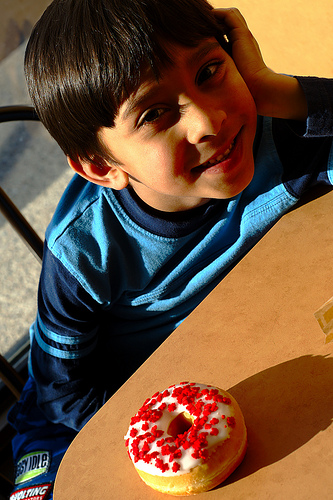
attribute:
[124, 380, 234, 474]
icing — red, white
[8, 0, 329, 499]
boy — pictured, light-skinned, sitting, young, smiling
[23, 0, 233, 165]
hair — pictured, short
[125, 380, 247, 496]
doughnut — pictured, creamy, sitting, brown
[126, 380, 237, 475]
cream — white, pictured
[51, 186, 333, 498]
table — pictured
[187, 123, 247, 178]
mouth — pictured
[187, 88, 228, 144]
nose — pictured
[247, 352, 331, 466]
shade — pictured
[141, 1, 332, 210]
shade — pictured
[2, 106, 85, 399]
chair — metal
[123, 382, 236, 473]
sprinkles — red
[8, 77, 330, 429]
shirt — blue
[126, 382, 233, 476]
frosting — white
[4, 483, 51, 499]
patch — red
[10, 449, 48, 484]
patch — lime green